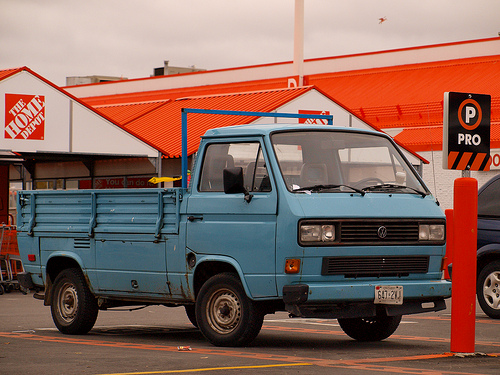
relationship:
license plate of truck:
[370, 284, 406, 304] [19, 103, 450, 344]